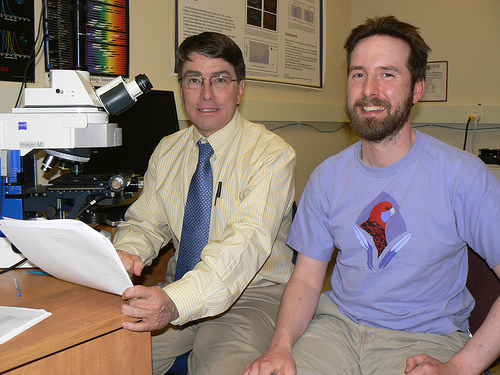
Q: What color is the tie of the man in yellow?
A: Blue.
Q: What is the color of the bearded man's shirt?
A: Purple.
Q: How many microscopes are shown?
A: One.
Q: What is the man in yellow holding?
A: A piece of paper.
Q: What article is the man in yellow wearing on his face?
A: Glasses.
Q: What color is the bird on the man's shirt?
A: Red.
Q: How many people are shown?
A: Two.